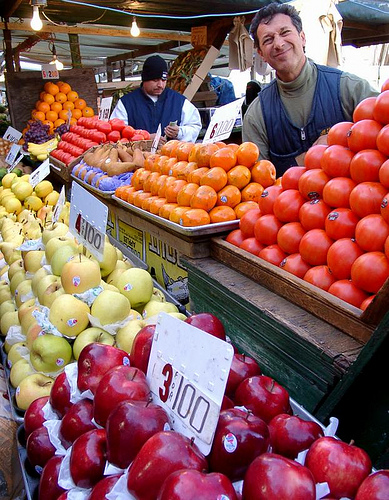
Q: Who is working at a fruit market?
A: A happy man.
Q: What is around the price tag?
A: Apples are around the price tag.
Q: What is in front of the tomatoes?
A: Apples are in front of the tomatoes.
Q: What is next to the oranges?
A: Tomatoes are next to the oranges.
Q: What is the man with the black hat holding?
A: The man is holding money.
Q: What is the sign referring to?
A: The sign is referring to apples.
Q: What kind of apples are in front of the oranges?
A: Granny smith apples are in front of the oranges.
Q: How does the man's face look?
A: The man is smiling.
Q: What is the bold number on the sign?
A: The bold number is a three.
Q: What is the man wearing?
A: The man is wearing a vest.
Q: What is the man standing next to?
A: The man is standing next to tomatoes.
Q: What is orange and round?
A: The oranges.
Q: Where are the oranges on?
A: Metal plate.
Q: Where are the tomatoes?
A: In wooden container.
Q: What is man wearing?
A: Blue vest.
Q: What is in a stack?
A: Oranges.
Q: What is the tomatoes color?
A: Red.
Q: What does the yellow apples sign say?
A: Four for one dollar.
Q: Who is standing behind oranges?
A: Middle aged man.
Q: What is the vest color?
A: Blue.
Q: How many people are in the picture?
A: Two.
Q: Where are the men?
A: Behind the fruit.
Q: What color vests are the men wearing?
A: Blue.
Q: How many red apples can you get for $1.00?
A: Three.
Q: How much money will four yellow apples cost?
A: $1.00.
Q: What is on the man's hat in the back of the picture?
A: A hat.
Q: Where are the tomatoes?
A: Above the red apples.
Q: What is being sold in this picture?
A: Produce.